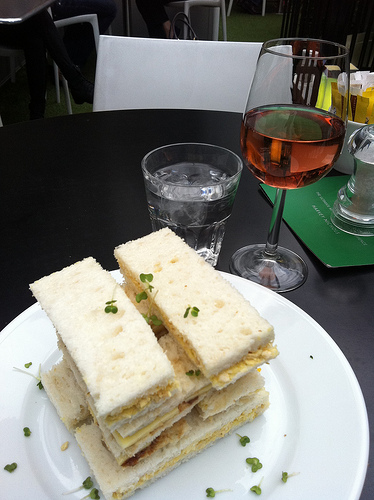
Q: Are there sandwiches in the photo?
A: Yes, there is a sandwich.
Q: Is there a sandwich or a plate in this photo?
A: Yes, there is a sandwich.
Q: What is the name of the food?
A: The food is a sandwich.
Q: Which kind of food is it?
A: The food is a sandwich.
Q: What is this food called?
A: This is a sandwich.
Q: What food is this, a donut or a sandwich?
A: This is a sandwich.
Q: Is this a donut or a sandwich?
A: This is a sandwich.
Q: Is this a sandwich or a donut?
A: This is a sandwich.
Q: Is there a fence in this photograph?
A: No, there are no fences.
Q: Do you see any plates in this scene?
A: Yes, there is a plate.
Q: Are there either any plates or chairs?
A: Yes, there is a plate.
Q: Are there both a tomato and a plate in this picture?
A: No, there is a plate but no tomatoes.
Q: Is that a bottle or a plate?
A: That is a plate.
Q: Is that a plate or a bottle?
A: That is a plate.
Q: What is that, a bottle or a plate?
A: That is a plate.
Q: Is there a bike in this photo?
A: No, there are no bikes.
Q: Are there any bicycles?
A: No, there are no bicycles.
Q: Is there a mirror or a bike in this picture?
A: No, there are no bikes or mirrors.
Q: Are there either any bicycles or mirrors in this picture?
A: No, there are no bicycles or mirrors.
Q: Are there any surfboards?
A: No, there are no surfboards.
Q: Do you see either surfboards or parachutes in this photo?
A: No, there are no surfboards or parachutes.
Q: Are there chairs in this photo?
A: Yes, there is a chair.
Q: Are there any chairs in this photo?
A: Yes, there is a chair.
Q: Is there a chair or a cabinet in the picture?
A: Yes, there is a chair.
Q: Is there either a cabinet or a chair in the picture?
A: Yes, there is a chair.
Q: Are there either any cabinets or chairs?
A: Yes, there is a chair.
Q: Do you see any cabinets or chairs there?
A: Yes, there is a chair.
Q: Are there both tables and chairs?
A: Yes, there are both a chair and a table.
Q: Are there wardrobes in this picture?
A: No, there are no wardrobes.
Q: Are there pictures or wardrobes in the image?
A: No, there are no wardrobes or pictures.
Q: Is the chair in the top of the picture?
A: Yes, the chair is in the top of the image.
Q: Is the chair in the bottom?
A: No, the chair is in the top of the image.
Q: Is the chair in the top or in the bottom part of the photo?
A: The chair is in the top of the image.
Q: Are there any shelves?
A: No, there are no shelves.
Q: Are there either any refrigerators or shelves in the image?
A: No, there are no shelves or refrigerators.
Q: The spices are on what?
A: The spices are on the leaves.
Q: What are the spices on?
A: The spices are on the leaves.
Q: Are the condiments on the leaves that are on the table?
A: Yes, the condiments are on the leaves.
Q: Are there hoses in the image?
A: No, there are no hoses.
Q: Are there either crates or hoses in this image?
A: No, there are no hoses or crates.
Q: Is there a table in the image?
A: Yes, there is a table.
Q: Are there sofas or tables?
A: Yes, there is a table.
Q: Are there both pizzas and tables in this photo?
A: No, there is a table but no pizzas.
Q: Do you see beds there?
A: No, there are no beds.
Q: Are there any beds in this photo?
A: No, there are no beds.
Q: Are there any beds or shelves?
A: No, there are no beds or shelves.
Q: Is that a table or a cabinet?
A: That is a table.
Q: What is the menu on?
A: The menu is on the table.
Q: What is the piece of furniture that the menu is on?
A: The piece of furniture is a table.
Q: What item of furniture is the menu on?
A: The menu is on the table.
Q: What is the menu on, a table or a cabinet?
A: The menu is on a table.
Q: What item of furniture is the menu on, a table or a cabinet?
A: The menu is on a table.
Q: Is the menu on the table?
A: Yes, the menu is on the table.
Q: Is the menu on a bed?
A: No, the menu is on the table.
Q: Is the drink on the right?
A: Yes, the drink is on the right of the image.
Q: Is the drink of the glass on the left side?
A: No, the drink is on the right of the image.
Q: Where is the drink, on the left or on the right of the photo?
A: The drink is on the right of the image.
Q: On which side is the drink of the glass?
A: The drink is on the right of the image.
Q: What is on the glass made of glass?
A: The drink is on the glass.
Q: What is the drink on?
A: The drink is on the glass.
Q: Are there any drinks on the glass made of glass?
A: Yes, there is a drink on the glass.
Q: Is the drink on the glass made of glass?
A: Yes, the drink is on the glass.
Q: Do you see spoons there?
A: No, there are no spoons.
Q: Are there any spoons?
A: No, there are no spoons.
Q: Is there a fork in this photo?
A: No, there are no forks.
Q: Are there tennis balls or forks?
A: No, there are no forks or tennis balls.